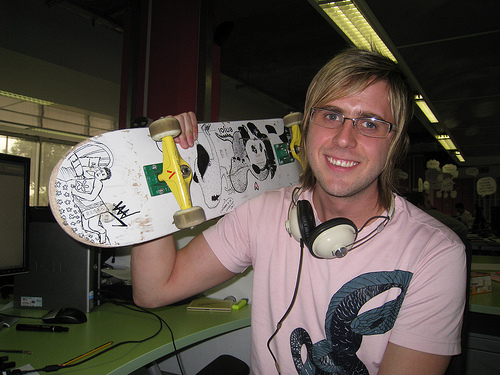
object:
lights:
[308, 2, 402, 61]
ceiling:
[268, 5, 499, 79]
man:
[130, 49, 466, 375]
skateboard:
[49, 110, 305, 249]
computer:
[1, 153, 109, 333]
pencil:
[61, 339, 111, 366]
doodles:
[197, 122, 287, 191]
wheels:
[172, 205, 207, 231]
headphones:
[284, 182, 396, 261]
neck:
[306, 192, 393, 228]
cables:
[9, 334, 154, 375]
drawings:
[416, 157, 460, 199]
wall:
[409, 140, 498, 215]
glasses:
[307, 104, 399, 138]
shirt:
[199, 185, 465, 375]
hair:
[307, 48, 404, 84]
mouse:
[41, 307, 88, 325]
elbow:
[128, 272, 198, 310]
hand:
[169, 111, 200, 149]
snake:
[288, 269, 414, 373]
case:
[93, 281, 132, 304]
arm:
[130, 192, 261, 309]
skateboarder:
[286, 62, 448, 267]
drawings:
[53, 141, 140, 247]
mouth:
[323, 150, 359, 172]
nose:
[329, 131, 356, 149]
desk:
[10, 298, 256, 375]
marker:
[14, 320, 74, 335]